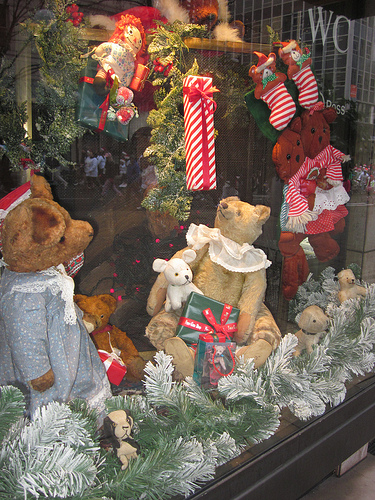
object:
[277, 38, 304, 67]
head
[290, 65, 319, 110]
stocking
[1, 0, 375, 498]
window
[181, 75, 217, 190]
christmas garland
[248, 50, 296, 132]
bear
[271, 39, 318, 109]
bear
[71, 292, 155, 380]
bear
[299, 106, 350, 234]
bear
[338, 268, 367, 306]
bear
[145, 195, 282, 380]
bears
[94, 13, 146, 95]
doll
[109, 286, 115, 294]
christmas lights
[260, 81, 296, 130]
stocking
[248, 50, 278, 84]
head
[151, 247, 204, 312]
dog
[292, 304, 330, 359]
dog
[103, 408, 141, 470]
black dog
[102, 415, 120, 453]
tan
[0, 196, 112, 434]
bear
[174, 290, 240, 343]
green/christmas garland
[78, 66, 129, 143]
present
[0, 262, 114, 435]
dress